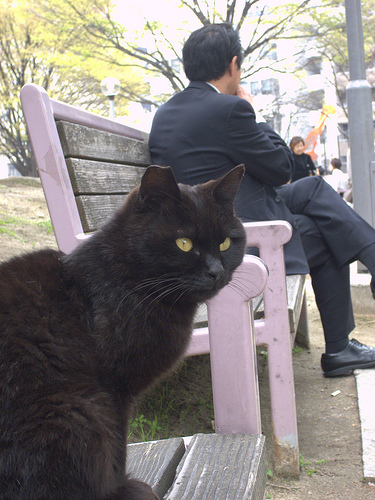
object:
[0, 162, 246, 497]
cat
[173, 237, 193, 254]
eye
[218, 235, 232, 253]
eye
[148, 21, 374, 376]
man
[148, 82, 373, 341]
suit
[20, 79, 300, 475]
bench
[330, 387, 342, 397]
cigarette butt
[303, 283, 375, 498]
ground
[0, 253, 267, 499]
bench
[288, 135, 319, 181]
woman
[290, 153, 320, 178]
coat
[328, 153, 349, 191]
woman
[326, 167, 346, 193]
coat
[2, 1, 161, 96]
tree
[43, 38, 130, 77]
leaves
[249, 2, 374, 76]
tree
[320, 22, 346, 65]
leaves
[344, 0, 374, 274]
pole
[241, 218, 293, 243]
arm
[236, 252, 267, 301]
arm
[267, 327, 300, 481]
leg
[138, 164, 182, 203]
ear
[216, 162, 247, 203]
ear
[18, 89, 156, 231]
back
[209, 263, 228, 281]
nose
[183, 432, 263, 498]
slat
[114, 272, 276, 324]
whiskers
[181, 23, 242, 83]
head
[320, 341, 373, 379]
shoe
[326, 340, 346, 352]
socks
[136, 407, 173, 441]
grass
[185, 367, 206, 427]
dirt